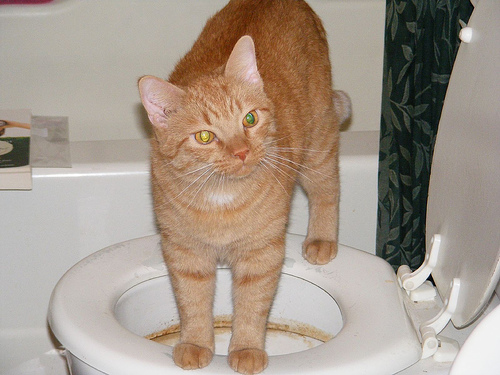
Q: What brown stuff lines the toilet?
A: Dirt.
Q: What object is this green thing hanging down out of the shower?
A: Shower curtain.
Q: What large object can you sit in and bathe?
A: Bathtub.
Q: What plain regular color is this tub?
A: White.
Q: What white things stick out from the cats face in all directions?
A: Whiskers.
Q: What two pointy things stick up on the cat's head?
A: Ears.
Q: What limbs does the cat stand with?
A: Legs.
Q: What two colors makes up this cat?
A: Orange and white.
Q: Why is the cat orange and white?
A: Genetics.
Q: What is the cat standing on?
A: The toilet.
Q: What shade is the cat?
A: Orange.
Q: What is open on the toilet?
A: The lid.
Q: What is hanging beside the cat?
A: A curtain.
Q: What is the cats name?
A: Scruffy.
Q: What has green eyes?
A: The cat.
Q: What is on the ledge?
A: A book.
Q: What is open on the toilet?
A: The lid.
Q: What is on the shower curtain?
A: Leaves.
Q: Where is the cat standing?
A: A toilet.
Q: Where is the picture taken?
A: A bathroom.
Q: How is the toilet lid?
A: Up.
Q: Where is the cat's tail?
A: In the air.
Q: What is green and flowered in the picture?
A: Shower curtain.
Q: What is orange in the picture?
A: Cat.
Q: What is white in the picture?
A: Toilet and tub.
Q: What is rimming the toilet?
A: Mineral stains.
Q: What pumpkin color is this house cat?
A: Orange.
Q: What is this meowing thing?
A: Cat.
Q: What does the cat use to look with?
A: Eyes.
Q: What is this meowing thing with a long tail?
A: Cat.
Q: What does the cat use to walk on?
A: Legs.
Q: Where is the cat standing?
A: In toilet.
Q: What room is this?
A: Bathroom.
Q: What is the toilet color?
A: White.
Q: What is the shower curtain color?
A: Green.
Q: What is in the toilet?
A: Dirt ring.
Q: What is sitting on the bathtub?
A: A book.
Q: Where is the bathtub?
A: Next to the toilet.